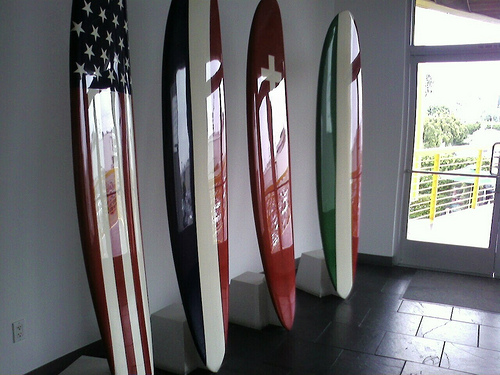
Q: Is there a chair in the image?
A: No, there are no chairs.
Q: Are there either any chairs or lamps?
A: No, there are no chairs or lamps.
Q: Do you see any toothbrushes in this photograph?
A: No, there are no toothbrushes.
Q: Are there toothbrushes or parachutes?
A: No, there are no toothbrushes or parachutes.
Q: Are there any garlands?
A: No, there are no garlands.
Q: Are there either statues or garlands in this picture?
A: No, there are no garlands or statues.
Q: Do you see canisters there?
A: No, there are no canisters.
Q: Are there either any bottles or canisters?
A: No, there are no canisters or bottles.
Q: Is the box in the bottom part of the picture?
A: Yes, the box is in the bottom of the image.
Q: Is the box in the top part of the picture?
A: No, the box is in the bottom of the image.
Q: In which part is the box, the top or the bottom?
A: The box is in the bottom of the image.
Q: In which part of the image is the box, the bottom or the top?
A: The box is in the bottom of the image.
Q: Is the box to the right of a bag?
A: No, the box is to the right of the surf board.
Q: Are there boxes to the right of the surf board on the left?
A: Yes, there is a box to the right of the surfboard.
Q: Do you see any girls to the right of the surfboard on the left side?
A: No, there is a box to the right of the surfboard.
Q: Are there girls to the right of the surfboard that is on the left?
A: No, there is a box to the right of the surfboard.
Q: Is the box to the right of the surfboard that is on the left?
A: Yes, the box is to the right of the surfboard.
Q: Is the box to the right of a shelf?
A: No, the box is to the right of the surfboard.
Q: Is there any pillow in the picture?
A: No, there are no pillows.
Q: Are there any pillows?
A: No, there are no pillows.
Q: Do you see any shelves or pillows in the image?
A: No, there are no pillows or shelves.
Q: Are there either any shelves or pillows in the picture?
A: No, there are no pillows or shelves.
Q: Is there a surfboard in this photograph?
A: Yes, there is a surfboard.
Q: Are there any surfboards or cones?
A: Yes, there is a surfboard.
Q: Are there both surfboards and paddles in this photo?
A: No, there is a surfboard but no paddles.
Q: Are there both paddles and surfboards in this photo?
A: No, there is a surfboard but no paddles.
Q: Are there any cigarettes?
A: No, there are no cigarettes.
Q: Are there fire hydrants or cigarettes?
A: No, there are no cigarettes or fire hydrants.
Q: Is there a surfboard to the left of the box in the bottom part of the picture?
A: Yes, there is a surfboard to the left of the box.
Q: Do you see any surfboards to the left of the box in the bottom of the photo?
A: Yes, there is a surfboard to the left of the box.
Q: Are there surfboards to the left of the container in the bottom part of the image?
A: Yes, there is a surfboard to the left of the box.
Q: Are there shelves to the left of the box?
A: No, there is a surfboard to the left of the box.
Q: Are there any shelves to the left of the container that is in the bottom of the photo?
A: No, there is a surfboard to the left of the box.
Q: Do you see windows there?
A: Yes, there is a window.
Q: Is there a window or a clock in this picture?
A: Yes, there is a window.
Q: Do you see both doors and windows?
A: Yes, there are both a window and a door.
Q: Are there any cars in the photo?
A: No, there are no cars.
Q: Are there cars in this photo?
A: No, there are no cars.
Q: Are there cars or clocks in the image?
A: No, there are no cars or clocks.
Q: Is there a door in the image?
A: Yes, there is a door.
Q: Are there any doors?
A: Yes, there is a door.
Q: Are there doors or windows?
A: Yes, there is a door.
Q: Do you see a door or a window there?
A: Yes, there is a door.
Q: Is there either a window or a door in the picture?
A: Yes, there is a door.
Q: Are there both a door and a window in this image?
A: Yes, there are both a door and a window.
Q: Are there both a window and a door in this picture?
A: Yes, there are both a door and a window.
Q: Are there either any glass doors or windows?
A: Yes, there is a glass door.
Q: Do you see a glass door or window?
A: Yes, there is a glass door.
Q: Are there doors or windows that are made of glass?
A: Yes, the door is made of glass.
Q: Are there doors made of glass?
A: Yes, there is a door that is made of glass.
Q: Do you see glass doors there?
A: Yes, there is a door that is made of glass.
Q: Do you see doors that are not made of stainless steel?
A: Yes, there is a door that is made of glass.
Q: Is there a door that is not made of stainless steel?
A: Yes, there is a door that is made of glass.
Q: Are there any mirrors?
A: No, there are no mirrors.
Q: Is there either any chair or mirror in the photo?
A: No, there are no mirrors or chairs.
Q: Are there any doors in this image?
A: Yes, there is a door.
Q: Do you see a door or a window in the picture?
A: Yes, there is a door.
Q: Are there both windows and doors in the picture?
A: Yes, there are both a door and windows.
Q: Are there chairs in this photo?
A: No, there are no chairs.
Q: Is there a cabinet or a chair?
A: No, there are no chairs or cabinets.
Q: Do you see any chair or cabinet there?
A: No, there are no chairs or cabinets.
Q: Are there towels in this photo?
A: No, there are no towels.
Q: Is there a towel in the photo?
A: No, there are no towels.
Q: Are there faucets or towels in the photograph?
A: No, there are no towels or faucets.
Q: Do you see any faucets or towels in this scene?
A: No, there are no towels or faucets.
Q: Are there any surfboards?
A: Yes, there is a surfboard.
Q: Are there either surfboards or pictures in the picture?
A: Yes, there is a surfboard.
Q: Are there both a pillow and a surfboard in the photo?
A: No, there is a surfboard but no pillows.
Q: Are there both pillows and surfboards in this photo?
A: No, there is a surfboard but no pillows.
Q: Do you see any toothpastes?
A: No, there are no toothpastes.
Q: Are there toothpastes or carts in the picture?
A: No, there are no toothpastes or carts.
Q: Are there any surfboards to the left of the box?
A: Yes, there is a surfboard to the left of the box.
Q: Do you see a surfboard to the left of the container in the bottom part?
A: Yes, there is a surfboard to the left of the box.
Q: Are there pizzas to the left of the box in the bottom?
A: No, there is a surfboard to the left of the box.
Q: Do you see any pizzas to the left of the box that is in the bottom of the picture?
A: No, there is a surfboard to the left of the box.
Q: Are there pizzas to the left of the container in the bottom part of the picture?
A: No, there is a surfboard to the left of the box.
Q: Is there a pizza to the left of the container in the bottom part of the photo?
A: No, there is a surfboard to the left of the box.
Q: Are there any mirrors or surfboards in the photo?
A: Yes, there is a surfboard.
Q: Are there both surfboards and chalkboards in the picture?
A: No, there is a surfboard but no chalkboards.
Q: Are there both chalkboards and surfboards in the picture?
A: No, there is a surfboard but no chalkboards.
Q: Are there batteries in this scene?
A: No, there are no batteries.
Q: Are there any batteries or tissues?
A: No, there are no batteries or tissues.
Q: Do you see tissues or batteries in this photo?
A: No, there are no batteries or tissues.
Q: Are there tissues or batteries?
A: No, there are no batteries or tissues.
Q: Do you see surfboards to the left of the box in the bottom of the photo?
A: Yes, there is a surfboard to the left of the box.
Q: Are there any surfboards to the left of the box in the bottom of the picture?
A: Yes, there is a surfboard to the left of the box.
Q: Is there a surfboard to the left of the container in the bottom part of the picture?
A: Yes, there is a surfboard to the left of the box.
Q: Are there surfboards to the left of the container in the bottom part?
A: Yes, there is a surfboard to the left of the box.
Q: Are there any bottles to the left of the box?
A: No, there is a surfboard to the left of the box.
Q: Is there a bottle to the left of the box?
A: No, there is a surfboard to the left of the box.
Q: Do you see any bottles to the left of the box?
A: No, there is a surfboard to the left of the box.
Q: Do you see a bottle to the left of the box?
A: No, there is a surfboard to the left of the box.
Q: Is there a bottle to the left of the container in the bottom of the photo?
A: No, there is a surfboard to the left of the box.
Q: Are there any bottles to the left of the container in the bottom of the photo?
A: No, there is a surfboard to the left of the box.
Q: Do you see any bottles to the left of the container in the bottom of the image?
A: No, there is a surfboard to the left of the box.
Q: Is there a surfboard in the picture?
A: Yes, there is a surfboard.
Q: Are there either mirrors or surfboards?
A: Yes, there is a surfboard.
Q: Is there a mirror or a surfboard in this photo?
A: Yes, there is a surfboard.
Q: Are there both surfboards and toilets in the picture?
A: No, there is a surfboard but no toilets.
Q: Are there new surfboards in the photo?
A: Yes, there is a new surfboard.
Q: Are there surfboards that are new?
A: Yes, there is a surfboard that is new.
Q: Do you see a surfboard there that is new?
A: Yes, there is a surfboard that is new.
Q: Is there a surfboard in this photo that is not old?
A: Yes, there is an new surfboard.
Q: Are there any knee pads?
A: No, there are no knee pads.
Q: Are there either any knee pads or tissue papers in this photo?
A: No, there are no knee pads or tissue papers.